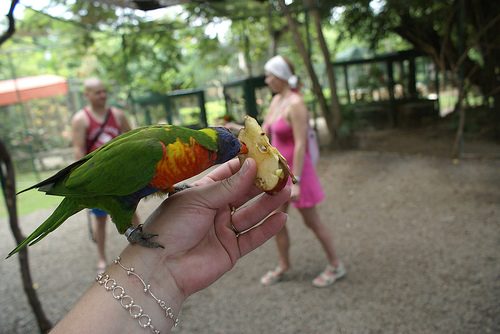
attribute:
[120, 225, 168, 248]
talons — black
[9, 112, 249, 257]
parrot — colorful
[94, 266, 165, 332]
bracelets — silver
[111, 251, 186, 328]
bracelets — silver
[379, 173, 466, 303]
floor — rocky, gray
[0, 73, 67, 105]
canopy — orange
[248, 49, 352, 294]
woman — pink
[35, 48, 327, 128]
man woman — facing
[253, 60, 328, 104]
headband — white, wide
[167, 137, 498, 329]
ground — brown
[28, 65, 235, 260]
bird — yellow, blue, red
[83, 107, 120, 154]
shirt — red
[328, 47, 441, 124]
structures — boxy, open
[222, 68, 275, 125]
structures — boxy, open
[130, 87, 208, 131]
structures — boxy, open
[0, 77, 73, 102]
canopy — orange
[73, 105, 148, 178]
shirt — red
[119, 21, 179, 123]
tree — green, rowed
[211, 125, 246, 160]
head — blue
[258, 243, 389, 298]
toes — black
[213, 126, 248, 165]
head — blue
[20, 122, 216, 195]
feathers — orange, yellow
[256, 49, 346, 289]
woman/sundress — pink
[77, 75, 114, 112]
head — white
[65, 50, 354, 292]
people — couple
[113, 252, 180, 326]
bracelet — white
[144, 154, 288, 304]
hand — person's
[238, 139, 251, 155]
beak — orange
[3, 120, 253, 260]
bird — green, orange